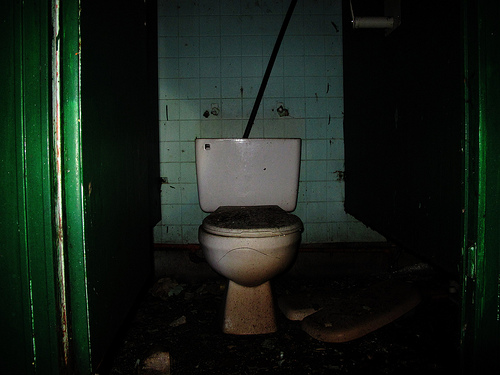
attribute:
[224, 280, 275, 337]
base — white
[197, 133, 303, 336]
toilet — white, porcelain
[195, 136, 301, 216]
tank lid — white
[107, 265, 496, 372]
floor — dirty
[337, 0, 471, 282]
structure — emerald green, stall, green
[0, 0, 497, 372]
bathroom — dirty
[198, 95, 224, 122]
tile — dirty, grimy, green, square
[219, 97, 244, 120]
tile — white, green, dirty, square, grimy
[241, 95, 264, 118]
tile — dirty, grimy, green, square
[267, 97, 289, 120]
tile — green, white, square, dirty, grimy, missing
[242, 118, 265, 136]
tile — square, dirty, white, green, grimy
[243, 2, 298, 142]
pole — black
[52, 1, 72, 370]
metal — grey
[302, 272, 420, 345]
lid — laying, brown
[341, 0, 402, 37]
handle — small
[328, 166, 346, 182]
marks — dark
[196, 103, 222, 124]
marks — dark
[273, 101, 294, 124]
marks — dark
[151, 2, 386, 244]
wall — tiled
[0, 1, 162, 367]
structure — emerald green